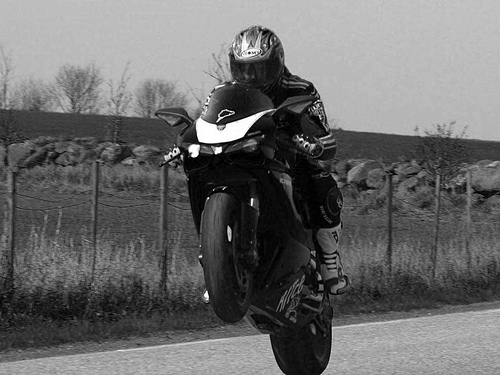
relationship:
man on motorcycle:
[217, 27, 345, 291] [153, 81, 337, 375]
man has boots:
[217, 27, 345, 291] [309, 221, 346, 293]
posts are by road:
[2, 163, 485, 293] [1, 299, 499, 374]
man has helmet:
[217, 27, 345, 291] [232, 25, 285, 80]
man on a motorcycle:
[217, 27, 345, 291] [153, 81, 337, 375]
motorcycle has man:
[153, 81, 337, 375] [217, 27, 345, 291]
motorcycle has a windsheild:
[153, 81, 337, 375] [209, 88, 264, 142]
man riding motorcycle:
[217, 27, 345, 291] [153, 81, 337, 375]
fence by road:
[7, 159, 500, 279] [1, 299, 499, 374]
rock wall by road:
[6, 136, 495, 176] [1, 299, 499, 374]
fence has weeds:
[7, 159, 500, 279] [10, 215, 495, 300]